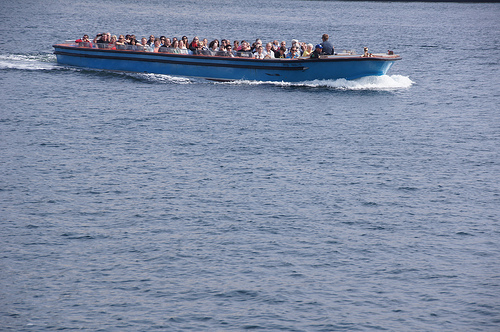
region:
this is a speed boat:
[36, 43, 412, 75]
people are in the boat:
[139, 33, 338, 58]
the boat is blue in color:
[308, 60, 330, 75]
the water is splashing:
[368, 73, 413, 92]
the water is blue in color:
[127, 145, 448, 322]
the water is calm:
[186, 118, 490, 317]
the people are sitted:
[211, 41, 292, 59]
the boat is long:
[108, 56, 367, 75]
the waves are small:
[125, 159, 412, 329]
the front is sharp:
[368, 48, 400, 75]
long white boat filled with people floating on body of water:
[45, 25, 403, 93]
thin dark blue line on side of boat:
[53, 48, 312, 73]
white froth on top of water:
[314, 72, 419, 94]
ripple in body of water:
[386, 182, 433, 194]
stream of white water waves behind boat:
[1, 43, 56, 74]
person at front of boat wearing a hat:
[315, 31, 335, 56]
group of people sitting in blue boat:
[81, 33, 313, 58]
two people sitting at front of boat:
[358, 44, 407, 77]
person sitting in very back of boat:
[66, 30, 93, 52]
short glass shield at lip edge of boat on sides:
[78, 46, 267, 64]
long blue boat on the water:
[49, 18, 409, 97]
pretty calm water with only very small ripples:
[26, 112, 468, 304]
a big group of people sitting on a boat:
[59, 23, 412, 83]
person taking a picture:
[96, 30, 110, 48]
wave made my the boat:
[331, 67, 414, 95]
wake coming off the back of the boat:
[4, 41, 65, 71]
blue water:
[2, 1, 499, 328]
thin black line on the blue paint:
[53, 50, 313, 77]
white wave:
[356, 71, 417, 91]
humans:
[71, 29, 354, 69]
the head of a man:
[320, 30, 330, 43]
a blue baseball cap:
[314, 42, 326, 52]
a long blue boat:
[48, 40, 400, 87]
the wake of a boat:
[0, 48, 67, 71]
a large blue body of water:
[1, 0, 498, 329]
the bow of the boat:
[358, 45, 403, 82]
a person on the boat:
[313, 26, 336, 57]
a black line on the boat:
[51, 45, 310, 74]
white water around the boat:
[226, 69, 418, 92]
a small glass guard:
[51, 37, 259, 61]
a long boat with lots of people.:
[43, 31, 412, 98]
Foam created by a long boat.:
[0, 53, 425, 93]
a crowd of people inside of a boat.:
[72, 27, 338, 57]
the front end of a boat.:
[330, 37, 401, 94]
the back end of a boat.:
[44, 11, 118, 77]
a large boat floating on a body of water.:
[1, 1, 497, 328]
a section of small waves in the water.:
[264, 180, 395, 237]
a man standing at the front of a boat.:
[315, 30, 343, 55]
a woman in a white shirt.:
[264, 36, 280, 63]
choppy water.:
[364, 68, 421, 90]